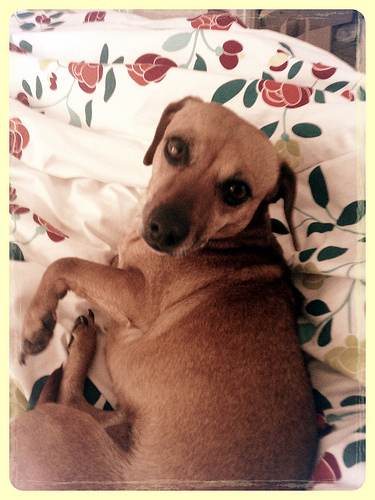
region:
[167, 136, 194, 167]
dog has brown eyes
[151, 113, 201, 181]
dog has brown eyes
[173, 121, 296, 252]
dog has brown eyes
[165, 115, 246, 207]
dog has brown eyes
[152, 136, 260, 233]
dog has brown eyes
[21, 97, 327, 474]
this is a dog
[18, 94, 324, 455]
the dog is small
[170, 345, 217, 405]
the fur is brown in color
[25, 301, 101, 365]
these are the dog's paws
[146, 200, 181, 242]
this is the dog's nose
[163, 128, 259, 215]
these are the dog's eyes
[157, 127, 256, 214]
the eyes are big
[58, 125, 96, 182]
this is a bed cover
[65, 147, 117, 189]
the bed cover is white in color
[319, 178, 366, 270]
drawings of some leaves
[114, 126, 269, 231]
the dog has eyes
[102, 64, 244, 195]
the dog has eyes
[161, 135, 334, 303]
the dog has eyes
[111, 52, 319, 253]
the dog has eyes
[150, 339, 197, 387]
stomach of a dog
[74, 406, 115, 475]
edge of a hip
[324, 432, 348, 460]
part of a sheet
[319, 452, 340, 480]
part of a sheet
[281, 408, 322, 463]
edge of a back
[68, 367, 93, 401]
edge of a dog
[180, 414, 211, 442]
tomach of a dog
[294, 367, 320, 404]
edge of a back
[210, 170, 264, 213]
Dog has brown eye.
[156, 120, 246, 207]
Dog has brown eye.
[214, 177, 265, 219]
Dog has black ring around eye.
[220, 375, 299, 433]
Dog has brown back fur.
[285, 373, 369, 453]
Dog is laying on top of blanket.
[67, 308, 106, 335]
Dog has black claws.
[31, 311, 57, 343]
dog has black pads on the bottom of feet.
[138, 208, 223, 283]
Dog has black nose.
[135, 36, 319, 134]
Floral print on blanket under dog.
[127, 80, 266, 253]
Dog has head lifted off of blanket.